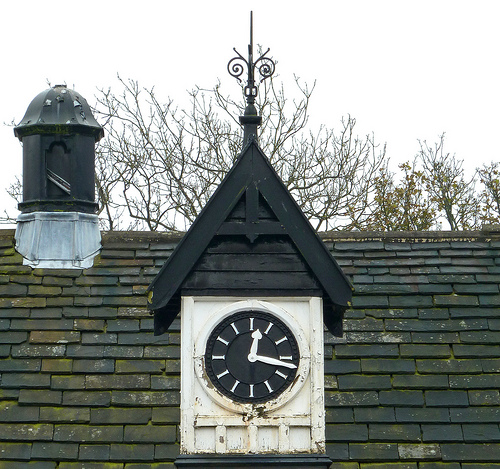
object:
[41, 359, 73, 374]
tile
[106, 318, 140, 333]
tile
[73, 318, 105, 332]
tile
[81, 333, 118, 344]
tile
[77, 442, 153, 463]
tile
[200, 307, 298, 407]
clock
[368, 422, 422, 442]
tile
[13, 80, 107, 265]
cylinder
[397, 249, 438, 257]
roofing tiles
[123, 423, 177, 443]
tile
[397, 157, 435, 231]
trees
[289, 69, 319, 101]
branches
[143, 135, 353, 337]
black triangle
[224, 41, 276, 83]
curlicue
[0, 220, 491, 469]
rooftop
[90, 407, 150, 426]
tile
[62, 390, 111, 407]
tile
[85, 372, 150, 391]
tile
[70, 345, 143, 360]
tile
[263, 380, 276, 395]
number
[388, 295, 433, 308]
tile